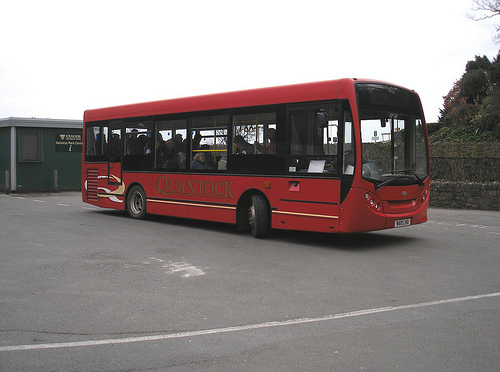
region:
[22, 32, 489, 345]
Picture of a red bus.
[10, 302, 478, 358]
White line painted on asphalt.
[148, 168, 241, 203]
The word QUANTOCK in gold letters.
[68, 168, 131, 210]
A large Q on back of bus.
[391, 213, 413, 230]
White license tag on front of bus.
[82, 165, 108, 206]
Vent on back of bus.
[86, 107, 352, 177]
Passenger windows on a bus.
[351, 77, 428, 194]
Front windshield on bus.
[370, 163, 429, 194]
Windshield wipers on bus.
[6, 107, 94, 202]
Building behind the bus.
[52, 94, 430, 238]
red and black bus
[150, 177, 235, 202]
gold and black sign on bus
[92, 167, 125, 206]
gold and white design on bus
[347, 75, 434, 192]
front window of bus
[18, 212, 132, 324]
gray street pavement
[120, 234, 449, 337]
gray street pavement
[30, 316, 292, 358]
gray street pavement with white lines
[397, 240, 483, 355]
gray street pavement with white lines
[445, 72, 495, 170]
tree with green leaves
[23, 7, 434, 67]
white clouds against sky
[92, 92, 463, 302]
windshield of large commerival busred commerical grade bus with white stripes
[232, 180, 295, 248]
wheel and tire on bus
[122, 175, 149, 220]
rear bus wheel and tire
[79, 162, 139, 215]
white Q logo design on back of bus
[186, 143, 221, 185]
passenger on commerical grade bus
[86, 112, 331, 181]
window along side of bus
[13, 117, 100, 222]
green building with white top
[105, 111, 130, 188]
emergency exit door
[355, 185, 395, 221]
front headlights on front of bus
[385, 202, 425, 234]
license tag on front of bus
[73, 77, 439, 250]
The red bus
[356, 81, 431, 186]
The windshield of the bus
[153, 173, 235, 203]
The gold writing on the bus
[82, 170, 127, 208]
The gold and white 'Q'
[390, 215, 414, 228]
The license plate of the bus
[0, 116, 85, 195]
The green building behind the bus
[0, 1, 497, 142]
The white sky behind the bus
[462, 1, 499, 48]
The bare tree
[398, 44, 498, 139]
The hill to the right of the bus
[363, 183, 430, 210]
The headlights of the bus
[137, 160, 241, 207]
Quantock on a bus.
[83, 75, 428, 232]
The bus is red.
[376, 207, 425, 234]
License plate on the bus.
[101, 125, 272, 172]
People on the bus.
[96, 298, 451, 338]
White line on the ground.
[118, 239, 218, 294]
Spill on the pavement.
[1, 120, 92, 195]
Green building behind the bus.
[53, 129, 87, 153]
Sign on the building.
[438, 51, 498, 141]
Trees on the hill.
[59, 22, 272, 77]
The sky is white.